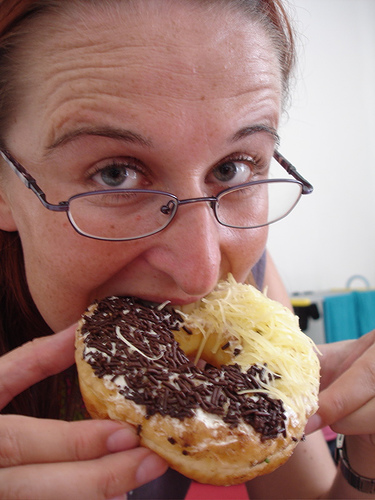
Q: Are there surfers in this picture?
A: No, there are no surfers.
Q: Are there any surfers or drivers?
A: No, there are no surfers or drivers.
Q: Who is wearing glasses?
A: The girl is wearing glasses.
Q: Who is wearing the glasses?
A: The girl is wearing glasses.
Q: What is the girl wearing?
A: The girl is wearing glasses.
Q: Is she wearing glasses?
A: Yes, the girl is wearing glasses.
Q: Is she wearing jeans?
A: No, the girl is wearing glasses.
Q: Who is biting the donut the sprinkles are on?
A: The girl is biting the donut.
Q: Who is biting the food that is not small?
A: The girl is biting the donut.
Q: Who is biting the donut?
A: The girl is biting the donut.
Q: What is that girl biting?
A: The girl is biting the doughnut.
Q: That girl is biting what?
A: The girl is biting the doughnut.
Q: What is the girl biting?
A: The girl is biting the doughnut.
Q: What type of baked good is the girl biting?
A: The girl is biting the doughnut.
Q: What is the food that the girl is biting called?
A: The food is a donut.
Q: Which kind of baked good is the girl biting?
A: The girl is biting the doughnut.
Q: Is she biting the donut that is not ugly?
A: Yes, the girl is biting the donut.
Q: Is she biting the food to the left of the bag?
A: Yes, the girl is biting the donut.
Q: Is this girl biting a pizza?
A: No, the girl is biting the donut.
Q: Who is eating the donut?
A: The girl is eating the donut.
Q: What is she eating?
A: The girl is eating a doughnut.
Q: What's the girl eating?
A: The girl is eating a doughnut.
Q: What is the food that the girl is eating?
A: The food is a donut.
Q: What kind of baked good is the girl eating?
A: The girl is eating a donut.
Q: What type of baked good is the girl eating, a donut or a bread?
A: The girl is eating a donut.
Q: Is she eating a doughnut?
A: Yes, the girl is eating a doughnut.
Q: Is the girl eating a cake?
A: No, the girl is eating a doughnut.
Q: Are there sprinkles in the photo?
A: Yes, there are sprinkles.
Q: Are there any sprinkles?
A: Yes, there are sprinkles.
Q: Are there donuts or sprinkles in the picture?
A: Yes, there are sprinkles.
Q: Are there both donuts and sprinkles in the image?
A: Yes, there are both sprinkles and a donut.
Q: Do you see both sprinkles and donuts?
A: Yes, there are both sprinkles and a donut.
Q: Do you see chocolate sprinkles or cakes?
A: Yes, there are chocolate sprinkles.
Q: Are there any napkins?
A: No, there are no napkins.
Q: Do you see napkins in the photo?
A: No, there are no napkins.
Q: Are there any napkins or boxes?
A: No, there are no napkins or boxes.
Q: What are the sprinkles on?
A: The sprinkles are on the doughnut.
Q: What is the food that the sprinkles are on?
A: The food is a donut.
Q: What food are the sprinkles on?
A: The sprinkles are on the doughnut.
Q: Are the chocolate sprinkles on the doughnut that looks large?
A: Yes, the sprinkles are on the doughnut.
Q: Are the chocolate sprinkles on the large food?
A: Yes, the sprinkles are on the doughnut.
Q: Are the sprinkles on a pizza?
A: No, the sprinkles are on the doughnut.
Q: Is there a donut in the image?
A: Yes, there is a donut.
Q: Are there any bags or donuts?
A: Yes, there is a donut.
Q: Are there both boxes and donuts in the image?
A: No, there is a donut but no boxes.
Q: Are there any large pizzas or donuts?
A: Yes, there is a large donut.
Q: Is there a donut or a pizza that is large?
A: Yes, the donut is large.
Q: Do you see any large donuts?
A: Yes, there is a large donut.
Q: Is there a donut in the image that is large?
A: Yes, there is a donut that is large.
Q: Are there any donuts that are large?
A: Yes, there is a donut that is large.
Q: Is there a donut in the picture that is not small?
A: Yes, there is a large donut.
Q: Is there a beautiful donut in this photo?
A: Yes, there is a beautiful donut.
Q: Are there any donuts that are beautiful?
A: Yes, there is a donut that is beautiful.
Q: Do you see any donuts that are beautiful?
A: Yes, there is a donut that is beautiful.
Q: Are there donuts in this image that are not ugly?
A: Yes, there is an beautiful donut.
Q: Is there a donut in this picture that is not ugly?
A: Yes, there is an beautiful donut.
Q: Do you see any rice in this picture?
A: No, there is no rice.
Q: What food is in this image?
A: The food is a donut.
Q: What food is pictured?
A: The food is a donut.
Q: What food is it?
A: The food is a donut.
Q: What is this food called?
A: That is a donut.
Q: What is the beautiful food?
A: The food is a donut.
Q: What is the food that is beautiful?
A: The food is a donut.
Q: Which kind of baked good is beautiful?
A: The baked good is a donut.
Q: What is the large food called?
A: The food is a donut.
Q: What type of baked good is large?
A: The baked good is a donut.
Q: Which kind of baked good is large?
A: The baked good is a donut.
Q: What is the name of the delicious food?
A: The food is a donut.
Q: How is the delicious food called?
A: The food is a donut.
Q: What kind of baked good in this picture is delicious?
A: The baked good is a donut.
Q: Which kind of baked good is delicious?
A: The baked good is a donut.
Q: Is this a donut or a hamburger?
A: This is a donut.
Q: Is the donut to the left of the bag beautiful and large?
A: Yes, the donut is beautiful and large.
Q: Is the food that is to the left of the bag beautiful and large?
A: Yes, the donut is beautiful and large.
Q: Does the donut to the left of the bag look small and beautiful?
A: No, the donut is beautiful but large.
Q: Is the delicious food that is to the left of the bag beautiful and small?
A: No, the donut is beautiful but large.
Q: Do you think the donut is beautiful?
A: Yes, the donut is beautiful.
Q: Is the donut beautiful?
A: Yes, the donut is beautiful.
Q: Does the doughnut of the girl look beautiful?
A: Yes, the doughnut is beautiful.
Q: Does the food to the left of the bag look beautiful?
A: Yes, the doughnut is beautiful.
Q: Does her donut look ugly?
A: No, the doughnut is beautiful.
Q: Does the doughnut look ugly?
A: No, the doughnut is beautiful.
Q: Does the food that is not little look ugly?
A: No, the doughnut is beautiful.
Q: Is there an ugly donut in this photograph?
A: No, there is a donut but it is beautiful.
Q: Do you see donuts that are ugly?
A: No, there is a donut but it is beautiful.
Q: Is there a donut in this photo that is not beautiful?
A: No, there is a donut but it is beautiful.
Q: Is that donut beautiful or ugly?
A: The donut is beautiful.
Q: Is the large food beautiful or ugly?
A: The donut is beautiful.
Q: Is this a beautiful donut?
A: Yes, this is a beautiful donut.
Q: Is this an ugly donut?
A: No, this is a beautiful donut.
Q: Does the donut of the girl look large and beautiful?
A: Yes, the donut is large and beautiful.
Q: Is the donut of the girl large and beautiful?
A: Yes, the donut is large and beautiful.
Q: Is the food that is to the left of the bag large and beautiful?
A: Yes, the donut is large and beautiful.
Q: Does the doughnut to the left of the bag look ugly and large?
A: No, the doughnut is large but beautiful.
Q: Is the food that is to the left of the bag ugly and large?
A: No, the doughnut is large but beautiful.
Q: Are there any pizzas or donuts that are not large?
A: No, there is a donut but it is large.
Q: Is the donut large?
A: Yes, the donut is large.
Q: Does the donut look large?
A: Yes, the donut is large.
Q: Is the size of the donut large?
A: Yes, the donut is large.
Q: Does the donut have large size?
A: Yes, the donut is large.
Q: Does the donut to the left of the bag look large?
A: Yes, the donut is large.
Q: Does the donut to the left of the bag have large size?
A: Yes, the donut is large.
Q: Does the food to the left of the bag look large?
A: Yes, the donut is large.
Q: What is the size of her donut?
A: The donut is large.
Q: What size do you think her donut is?
A: The donut is large.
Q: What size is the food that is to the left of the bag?
A: The donut is large.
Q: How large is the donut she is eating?
A: The doughnut is large.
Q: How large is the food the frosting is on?
A: The doughnut is large.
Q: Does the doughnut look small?
A: No, the doughnut is large.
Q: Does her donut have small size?
A: No, the doughnut is large.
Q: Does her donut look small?
A: No, the doughnut is large.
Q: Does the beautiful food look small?
A: No, the doughnut is large.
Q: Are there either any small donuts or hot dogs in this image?
A: No, there is a donut but it is large.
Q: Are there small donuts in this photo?
A: No, there is a donut but it is large.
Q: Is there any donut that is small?
A: No, there is a donut but it is large.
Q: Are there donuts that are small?
A: No, there is a donut but it is large.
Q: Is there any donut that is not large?
A: No, there is a donut but it is large.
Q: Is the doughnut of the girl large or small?
A: The donut is large.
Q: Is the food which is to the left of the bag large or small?
A: The donut is large.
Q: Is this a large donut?
A: Yes, this is a large donut.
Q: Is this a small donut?
A: No, this is a large donut.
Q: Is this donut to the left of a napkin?
A: No, the donut is to the left of the bag.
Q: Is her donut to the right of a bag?
A: No, the donut is to the left of a bag.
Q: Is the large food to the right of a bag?
A: No, the donut is to the left of a bag.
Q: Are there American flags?
A: No, there are no American flags.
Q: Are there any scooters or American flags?
A: No, there are no American flags or scooters.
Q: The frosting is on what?
A: The frosting is on the doughnut.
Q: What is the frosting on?
A: The frosting is on the doughnut.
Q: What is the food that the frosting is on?
A: The food is a donut.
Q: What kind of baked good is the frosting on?
A: The frosting is on the donut.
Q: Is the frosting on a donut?
A: Yes, the frosting is on a donut.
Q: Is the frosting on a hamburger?
A: No, the frosting is on a donut.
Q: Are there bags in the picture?
A: Yes, there is a bag.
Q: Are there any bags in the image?
A: Yes, there is a bag.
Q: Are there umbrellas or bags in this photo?
A: Yes, there is a bag.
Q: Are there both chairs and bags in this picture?
A: No, there is a bag but no chairs.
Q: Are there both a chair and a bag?
A: No, there is a bag but no chairs.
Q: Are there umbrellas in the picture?
A: No, there are no umbrellas.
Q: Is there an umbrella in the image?
A: No, there are no umbrellas.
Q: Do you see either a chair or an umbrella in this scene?
A: No, there are no umbrellas or chairs.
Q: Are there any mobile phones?
A: No, there are no mobile phones.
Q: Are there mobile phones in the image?
A: No, there are no mobile phones.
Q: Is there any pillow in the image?
A: No, there are no pillows.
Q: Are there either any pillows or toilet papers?
A: No, there are no pillows or toilet papers.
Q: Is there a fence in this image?
A: No, there are no fences.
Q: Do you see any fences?
A: No, there are no fences.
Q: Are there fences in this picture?
A: No, there are no fences.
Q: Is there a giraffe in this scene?
A: No, there are no giraffes.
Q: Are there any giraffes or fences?
A: No, there are no giraffes or fences.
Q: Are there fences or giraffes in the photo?
A: No, there are no giraffes or fences.